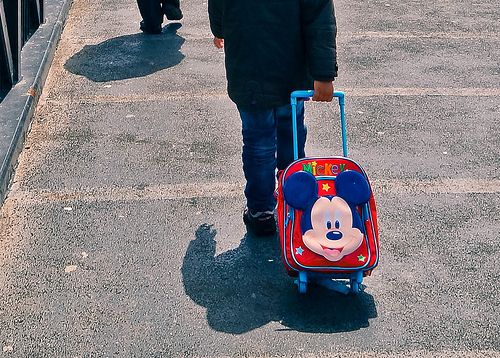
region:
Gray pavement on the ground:
[27, 202, 178, 344]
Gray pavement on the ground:
[63, 87, 214, 174]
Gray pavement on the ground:
[392, 56, 488, 343]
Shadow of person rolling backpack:
[156, 204, 242, 332]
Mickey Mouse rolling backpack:
[265, 145, 416, 355]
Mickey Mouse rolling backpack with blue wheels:
[257, 145, 392, 310]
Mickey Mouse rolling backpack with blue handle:
[257, 80, 399, 275]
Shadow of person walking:
[79, 18, 194, 117]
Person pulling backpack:
[215, 6, 366, 128]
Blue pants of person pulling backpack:
[208, 77, 309, 240]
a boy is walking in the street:
[205, 0, 341, 233]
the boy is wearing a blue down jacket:
[207, 0, 339, 116]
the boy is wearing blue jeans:
[237, 92, 307, 214]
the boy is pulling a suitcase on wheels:
[210, 5, 380, 296]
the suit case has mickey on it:
[277, 86, 378, 292]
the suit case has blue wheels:
[295, 265, 366, 296]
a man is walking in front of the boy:
[130, 0, 340, 230]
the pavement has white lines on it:
[5, 1, 491, 348]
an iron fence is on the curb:
[7, 5, 77, 206]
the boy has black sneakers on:
[242, 202, 279, 241]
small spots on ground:
[53, 216, 108, 288]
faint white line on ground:
[41, 174, 164, 212]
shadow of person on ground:
[70, 27, 218, 117]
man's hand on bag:
[310, 68, 342, 103]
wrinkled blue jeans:
[218, 100, 285, 228]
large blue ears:
[281, 165, 333, 224]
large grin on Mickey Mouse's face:
[300, 223, 386, 262]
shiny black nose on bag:
[323, 229, 369, 241]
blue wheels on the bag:
[288, 273, 390, 304]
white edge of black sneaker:
[233, 195, 294, 233]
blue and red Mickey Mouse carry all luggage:
[271, 83, 385, 294]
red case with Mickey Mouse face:
[273, 150, 381, 305]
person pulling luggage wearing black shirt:
[203, 0, 348, 243]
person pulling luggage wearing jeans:
[201, 2, 380, 294]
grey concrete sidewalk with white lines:
[2, 0, 497, 357]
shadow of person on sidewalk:
[175, 197, 308, 331]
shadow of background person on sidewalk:
[62, 15, 190, 92]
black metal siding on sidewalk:
[3, 0, 68, 192]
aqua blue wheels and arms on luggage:
[274, 84, 380, 291]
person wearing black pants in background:
[131, 0, 186, 53]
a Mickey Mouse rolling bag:
[275, 83, 379, 294]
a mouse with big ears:
[276, 165, 378, 265]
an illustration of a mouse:
[277, 163, 375, 265]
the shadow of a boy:
[180, 224, 281, 338]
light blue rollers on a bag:
[295, 273, 377, 294]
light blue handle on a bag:
[287, 84, 352, 160]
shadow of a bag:
[276, 276, 373, 332]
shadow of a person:
[60, 17, 185, 86]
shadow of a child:
[62, 17, 184, 84]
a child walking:
[205, 0, 340, 237]